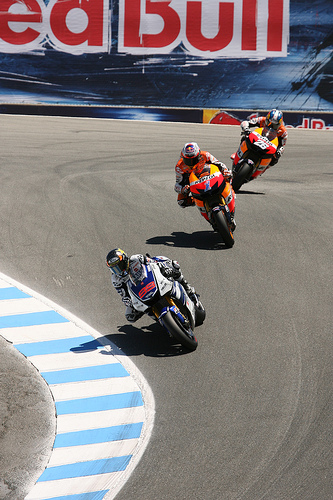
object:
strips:
[47, 321, 127, 467]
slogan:
[0, 0, 292, 60]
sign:
[0, 0, 332, 129]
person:
[174, 142, 237, 248]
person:
[105, 247, 196, 323]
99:
[138, 281, 155, 299]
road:
[13, 114, 330, 334]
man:
[174, 142, 233, 210]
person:
[230, 109, 288, 177]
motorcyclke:
[105, 141, 237, 351]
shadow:
[234, 190, 266, 195]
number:
[138, 281, 155, 299]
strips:
[0, 271, 156, 498]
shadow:
[145, 230, 233, 251]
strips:
[23, 357, 176, 496]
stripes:
[17, 309, 111, 427]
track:
[156, 308, 326, 456]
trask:
[41, 165, 156, 228]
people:
[106, 109, 288, 352]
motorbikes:
[231, 127, 279, 193]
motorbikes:
[185, 163, 236, 247]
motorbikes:
[127, 253, 206, 351]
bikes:
[174, 108, 288, 248]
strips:
[3, 307, 70, 328]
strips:
[15, 336, 103, 352]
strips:
[25, 353, 125, 382]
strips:
[52, 380, 142, 411]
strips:
[60, 415, 131, 479]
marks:
[63, 140, 203, 284]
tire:
[207, 194, 234, 248]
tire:
[160, 306, 198, 350]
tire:
[194, 300, 206, 324]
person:
[105, 247, 206, 351]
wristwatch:
[106, 247, 130, 279]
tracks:
[232, 307, 324, 498]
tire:
[229, 158, 251, 193]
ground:
[0, 113, 332, 500]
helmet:
[105, 248, 130, 278]